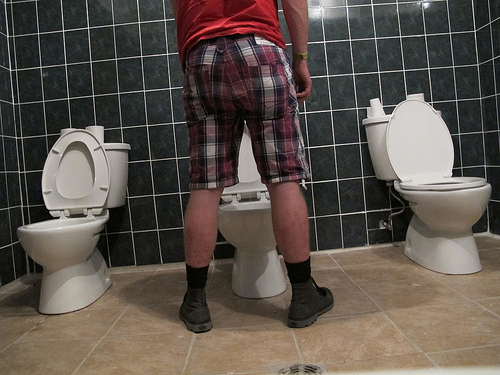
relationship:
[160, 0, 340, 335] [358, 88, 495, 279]
man using toilet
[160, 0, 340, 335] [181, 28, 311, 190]
man wearing shorts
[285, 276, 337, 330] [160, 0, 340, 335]
shoe of man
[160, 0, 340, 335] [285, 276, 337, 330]
man wearing shoe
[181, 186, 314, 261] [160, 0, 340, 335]
legs of man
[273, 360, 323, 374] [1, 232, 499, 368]
drain on ground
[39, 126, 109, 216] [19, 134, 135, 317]
seat of toilet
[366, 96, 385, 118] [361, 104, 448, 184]
toilet paper on tank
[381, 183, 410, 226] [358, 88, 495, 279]
hose to toilet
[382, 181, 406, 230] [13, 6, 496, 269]
hose into wall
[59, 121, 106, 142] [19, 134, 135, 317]
toilet paper on top of toilet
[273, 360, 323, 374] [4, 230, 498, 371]
drain in floor